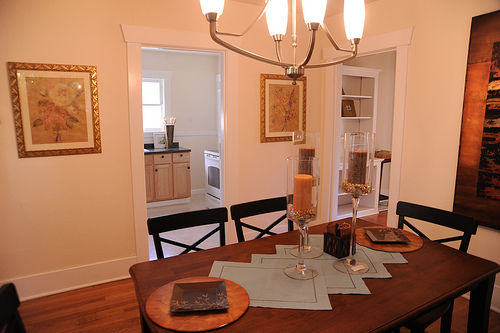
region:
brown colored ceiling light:
[183, 2, 430, 70]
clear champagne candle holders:
[275, 136, 395, 258]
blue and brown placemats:
[232, 246, 427, 331]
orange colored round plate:
[141, 246, 233, 331]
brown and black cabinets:
[133, 152, 222, 199]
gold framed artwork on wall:
[9, 47, 315, 168]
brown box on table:
[324, 215, 366, 270]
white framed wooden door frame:
[113, 18, 278, 245]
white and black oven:
[199, 149, 232, 210]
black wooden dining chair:
[154, 206, 292, 246]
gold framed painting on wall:
[1, 55, 108, 162]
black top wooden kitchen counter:
[146, 138, 197, 208]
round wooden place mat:
[138, 275, 255, 332]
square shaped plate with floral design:
[166, 278, 234, 317]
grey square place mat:
[199, 247, 335, 321]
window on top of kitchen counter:
[141, 73, 169, 136]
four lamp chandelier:
[196, 0, 377, 90]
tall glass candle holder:
[335, 126, 381, 278]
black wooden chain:
[137, 203, 236, 260]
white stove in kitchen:
[198, 144, 223, 208]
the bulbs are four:
[191, 9, 361, 66]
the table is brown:
[215, 235, 399, 329]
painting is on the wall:
[5, 55, 125, 152]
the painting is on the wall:
[251, 75, 321, 141]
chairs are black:
[146, 202, 243, 266]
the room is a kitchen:
[141, 66, 218, 230]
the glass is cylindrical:
[277, 149, 333, 293]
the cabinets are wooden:
[155, 157, 187, 202]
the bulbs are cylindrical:
[200, 6, 372, 43]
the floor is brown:
[54, 292, 124, 322]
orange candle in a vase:
[291, 170, 314, 215]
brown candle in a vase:
[346, 146, 366, 184]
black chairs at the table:
[143, 193, 300, 260]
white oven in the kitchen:
[201, 144, 228, 210]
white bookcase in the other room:
[336, 61, 383, 221]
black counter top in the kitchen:
[143, 135, 195, 158]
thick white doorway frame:
[116, 20, 243, 260]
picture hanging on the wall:
[3, 58, 103, 160]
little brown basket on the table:
[321, 218, 358, 260]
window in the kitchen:
[137, 68, 173, 138]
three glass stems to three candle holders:
[271, 223, 368, 291]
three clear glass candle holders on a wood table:
[273, 130, 369, 280]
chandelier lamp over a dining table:
[172, 0, 376, 87]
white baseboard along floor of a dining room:
[1, 256, 141, 304]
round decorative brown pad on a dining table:
[140, 273, 249, 330]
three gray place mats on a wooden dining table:
[198, 225, 416, 311]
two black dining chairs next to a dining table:
[146, 191, 299, 259]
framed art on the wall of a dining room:
[3, 59, 105, 158]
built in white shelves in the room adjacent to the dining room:
[329, 60, 381, 232]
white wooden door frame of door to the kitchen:
[116, 18, 251, 262]